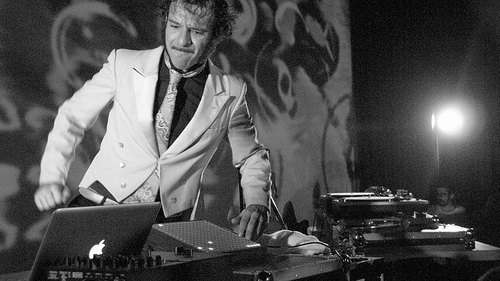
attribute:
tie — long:
[157, 42, 204, 156]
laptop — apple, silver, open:
[16, 198, 162, 280]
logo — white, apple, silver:
[88, 238, 107, 262]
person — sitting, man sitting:
[430, 182, 467, 222]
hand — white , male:
[235, 205, 265, 238]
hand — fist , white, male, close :
[37, 183, 70, 211]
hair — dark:
[153, 0, 243, 38]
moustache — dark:
[169, 44, 196, 58]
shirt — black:
[136, 54, 216, 160]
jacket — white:
[39, 44, 275, 218]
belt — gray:
[78, 180, 140, 223]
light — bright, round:
[434, 103, 467, 137]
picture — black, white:
[3, 3, 499, 277]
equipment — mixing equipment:
[45, 240, 230, 278]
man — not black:
[25, 0, 286, 255]